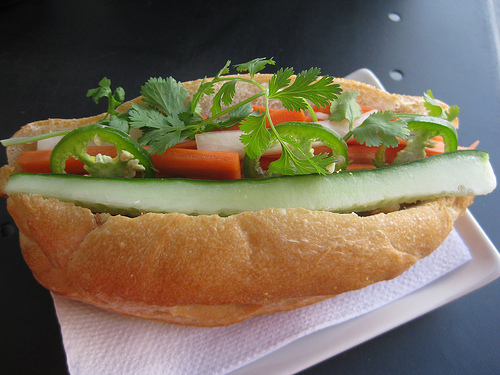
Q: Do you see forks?
A: No, there are no forks.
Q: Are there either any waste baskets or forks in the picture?
A: No, there are no forks or waste baskets.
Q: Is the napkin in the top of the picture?
A: No, the napkin is in the bottom of the image.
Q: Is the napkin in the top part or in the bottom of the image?
A: The napkin is in the bottom of the image.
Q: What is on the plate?
A: The napkin is on the plate.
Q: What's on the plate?
A: The napkin is on the plate.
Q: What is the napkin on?
A: The napkin is on the plate.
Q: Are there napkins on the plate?
A: Yes, there is a napkin on the plate.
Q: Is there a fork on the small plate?
A: No, there is a napkin on the plate.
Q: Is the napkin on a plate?
A: Yes, the napkin is on a plate.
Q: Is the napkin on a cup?
A: No, the napkin is on a plate.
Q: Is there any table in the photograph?
A: Yes, there is a table.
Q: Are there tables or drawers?
A: Yes, there is a table.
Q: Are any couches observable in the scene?
A: No, there are no couches.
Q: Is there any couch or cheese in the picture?
A: No, there are no couches or cheese.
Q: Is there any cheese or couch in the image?
A: No, there are no couches or cheese.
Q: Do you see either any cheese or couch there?
A: No, there are no couches or cheese.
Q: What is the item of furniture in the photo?
A: The piece of furniture is a table.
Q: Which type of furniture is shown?
A: The furniture is a table.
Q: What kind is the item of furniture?
A: The piece of furniture is a table.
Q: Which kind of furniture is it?
A: The piece of furniture is a table.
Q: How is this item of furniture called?
A: This is a table.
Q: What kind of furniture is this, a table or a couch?
A: This is a table.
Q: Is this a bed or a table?
A: This is a table.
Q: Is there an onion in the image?
A: Yes, there is an onion.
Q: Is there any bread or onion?
A: Yes, there is an onion.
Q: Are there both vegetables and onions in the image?
A: Yes, there are both an onion and a vegetable.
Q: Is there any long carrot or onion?
A: Yes, there is a long onion.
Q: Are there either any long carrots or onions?
A: Yes, there is a long onion.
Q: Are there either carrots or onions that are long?
A: Yes, the onion is long.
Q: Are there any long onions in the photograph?
A: Yes, there is a long onion.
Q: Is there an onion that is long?
A: Yes, there is an onion that is long.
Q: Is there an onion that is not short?
A: Yes, there is a long onion.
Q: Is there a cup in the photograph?
A: No, there are no cups.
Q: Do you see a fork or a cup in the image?
A: No, there are no cups or forks.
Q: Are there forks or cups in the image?
A: No, there are no cups or forks.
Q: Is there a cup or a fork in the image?
A: No, there are no cups or forks.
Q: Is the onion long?
A: Yes, the onion is long.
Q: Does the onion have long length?
A: Yes, the onion is long.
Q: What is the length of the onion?
A: The onion is long.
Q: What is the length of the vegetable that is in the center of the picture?
A: The onion is long.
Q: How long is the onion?
A: The onion is long.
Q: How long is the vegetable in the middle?
A: The onion is long.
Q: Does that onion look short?
A: No, the onion is long.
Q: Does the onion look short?
A: No, the onion is long.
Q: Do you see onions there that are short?
A: No, there is an onion but it is long.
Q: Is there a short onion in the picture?
A: No, there is an onion but it is long.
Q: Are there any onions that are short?
A: No, there is an onion but it is long.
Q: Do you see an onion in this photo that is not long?
A: No, there is an onion but it is long.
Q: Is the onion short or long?
A: The onion is long.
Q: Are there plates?
A: Yes, there is a plate.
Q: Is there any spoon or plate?
A: Yes, there is a plate.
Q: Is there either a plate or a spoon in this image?
A: Yes, there is a plate.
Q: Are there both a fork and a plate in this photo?
A: No, there is a plate but no forks.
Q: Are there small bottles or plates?
A: Yes, there is a small plate.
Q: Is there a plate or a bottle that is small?
A: Yes, the plate is small.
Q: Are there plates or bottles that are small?
A: Yes, the plate is small.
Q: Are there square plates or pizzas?
A: Yes, there is a square plate.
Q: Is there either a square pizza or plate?
A: Yes, there is a square plate.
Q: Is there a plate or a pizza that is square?
A: Yes, the plate is square.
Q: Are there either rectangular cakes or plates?
A: Yes, there is a rectangular plate.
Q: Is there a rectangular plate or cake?
A: Yes, there is a rectangular plate.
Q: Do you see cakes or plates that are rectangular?
A: Yes, the plate is rectangular.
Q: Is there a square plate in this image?
A: Yes, there is a square plate.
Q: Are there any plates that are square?
A: Yes, there is a plate that is square.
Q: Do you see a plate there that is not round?
A: Yes, there is a square plate.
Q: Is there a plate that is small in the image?
A: Yes, there is a small plate.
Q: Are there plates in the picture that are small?
A: Yes, there is a plate that is small.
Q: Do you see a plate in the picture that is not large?
A: Yes, there is a small plate.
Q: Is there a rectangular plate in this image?
A: Yes, there is a rectangular plate.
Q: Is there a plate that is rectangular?
A: Yes, there is a plate that is rectangular.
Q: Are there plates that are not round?
A: Yes, there is a rectangular plate.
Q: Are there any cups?
A: No, there are no cups.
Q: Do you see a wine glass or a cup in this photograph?
A: No, there are no cups or wine glasses.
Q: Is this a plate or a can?
A: This is a plate.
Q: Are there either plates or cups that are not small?
A: No, there is a plate but it is small.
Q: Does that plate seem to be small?
A: Yes, the plate is small.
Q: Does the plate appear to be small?
A: Yes, the plate is small.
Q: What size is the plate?
A: The plate is small.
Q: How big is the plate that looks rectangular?
A: The plate is small.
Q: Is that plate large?
A: No, the plate is small.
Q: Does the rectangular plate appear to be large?
A: No, the plate is small.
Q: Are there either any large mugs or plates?
A: No, there is a plate but it is small.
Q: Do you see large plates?
A: No, there is a plate but it is small.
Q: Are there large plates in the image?
A: No, there is a plate but it is small.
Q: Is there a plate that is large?
A: No, there is a plate but it is small.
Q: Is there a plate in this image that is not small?
A: No, there is a plate but it is small.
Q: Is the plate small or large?
A: The plate is small.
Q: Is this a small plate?
A: Yes, this is a small plate.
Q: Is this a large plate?
A: No, this is a small plate.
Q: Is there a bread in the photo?
A: Yes, there is a bread.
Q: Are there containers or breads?
A: Yes, there is a bread.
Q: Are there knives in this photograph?
A: No, there are no knives.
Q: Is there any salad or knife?
A: No, there are no knives or salad.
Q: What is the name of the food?
A: The food is a bread.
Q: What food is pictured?
A: The food is a bread.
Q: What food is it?
A: The food is a bread.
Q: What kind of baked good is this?
A: This is a bread.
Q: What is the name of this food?
A: This is a bread.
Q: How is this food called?
A: This is a bread.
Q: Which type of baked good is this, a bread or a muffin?
A: This is a bread.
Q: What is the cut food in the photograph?
A: The food is a bread.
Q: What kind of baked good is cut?
A: The baked good is a bread.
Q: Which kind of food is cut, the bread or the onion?
A: The bread is cut.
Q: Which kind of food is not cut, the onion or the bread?
A: The onion is not cut.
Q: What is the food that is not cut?
A: The food is an onion.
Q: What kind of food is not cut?
A: The food is an onion.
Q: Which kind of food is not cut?
A: The food is an onion.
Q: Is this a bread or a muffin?
A: This is a bread.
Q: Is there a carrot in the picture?
A: Yes, there are carrots.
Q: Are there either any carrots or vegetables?
A: Yes, there are carrots.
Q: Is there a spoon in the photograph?
A: No, there are no spoons.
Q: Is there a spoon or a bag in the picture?
A: No, there are no spoons or bags.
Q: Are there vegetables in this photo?
A: Yes, there are vegetables.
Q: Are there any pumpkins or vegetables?
A: Yes, there are vegetables.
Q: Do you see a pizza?
A: No, there are no pizzas.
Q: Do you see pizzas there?
A: No, there are no pizzas.